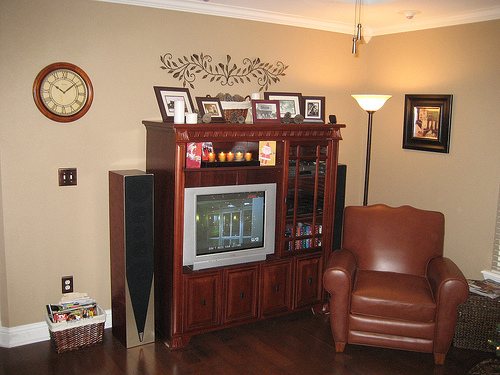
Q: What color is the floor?
A: Brown.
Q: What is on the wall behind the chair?
A: A picture.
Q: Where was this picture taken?
A: A livingroom.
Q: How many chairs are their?
A: 1.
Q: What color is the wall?
A: Tan.